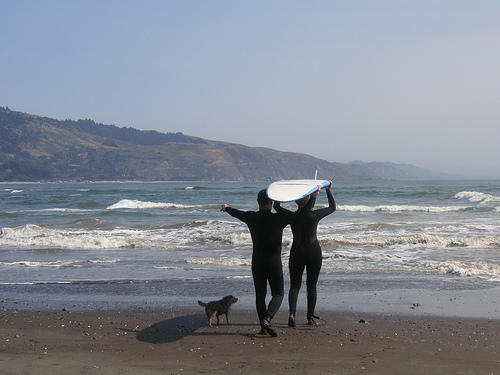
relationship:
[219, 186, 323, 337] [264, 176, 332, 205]
people carrying a surfboard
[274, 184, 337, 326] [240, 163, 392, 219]
person carrying a surfboard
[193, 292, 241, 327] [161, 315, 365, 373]
dog in sand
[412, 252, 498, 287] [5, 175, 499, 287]
wave in water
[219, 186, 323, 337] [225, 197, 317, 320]
people in wetsuits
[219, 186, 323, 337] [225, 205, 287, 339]
people in wet suit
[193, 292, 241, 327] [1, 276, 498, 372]
dog on beach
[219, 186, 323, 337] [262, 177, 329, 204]
people carrying surfboard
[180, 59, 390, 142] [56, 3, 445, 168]
clouds in sky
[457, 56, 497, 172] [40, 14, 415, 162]
clouds in sky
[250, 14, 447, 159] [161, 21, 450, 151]
clouds in sky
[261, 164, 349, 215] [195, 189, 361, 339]
surfboard carried by people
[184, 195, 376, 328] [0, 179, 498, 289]
people approaching ocean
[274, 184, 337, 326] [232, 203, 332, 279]
person wearing wetsuits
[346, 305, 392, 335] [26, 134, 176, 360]
brown rock strewn on beach